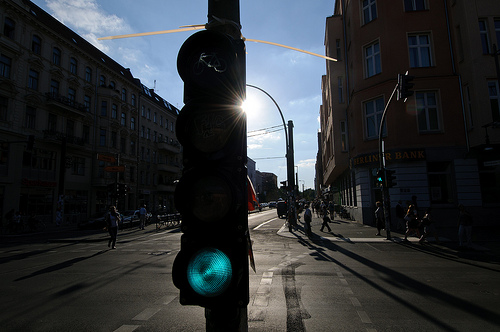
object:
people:
[373, 202, 386, 236]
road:
[0, 202, 494, 327]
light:
[170, 26, 246, 312]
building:
[1, 5, 181, 235]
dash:
[115, 286, 188, 332]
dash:
[242, 200, 292, 241]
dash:
[261, 200, 302, 276]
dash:
[329, 251, 378, 331]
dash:
[248, 271, 274, 332]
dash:
[263, 249, 313, 272]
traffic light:
[173, 239, 243, 306]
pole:
[170, 11, 273, 328]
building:
[317, 0, 494, 238]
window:
[362, 41, 383, 78]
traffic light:
[169, 28, 249, 306]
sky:
[32, 0, 318, 192]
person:
[106, 205, 122, 248]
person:
[303, 203, 313, 236]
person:
[319, 205, 334, 233]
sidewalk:
[277, 155, 471, 241]